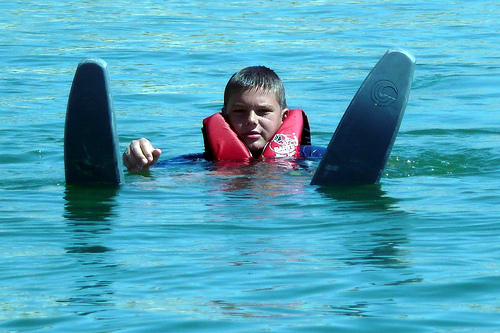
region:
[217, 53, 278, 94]
Person has short hair.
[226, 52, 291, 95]
Person has light brown hair.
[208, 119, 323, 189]
Person wearing red life vest.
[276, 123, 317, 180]
White logo on red vest.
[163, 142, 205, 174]
Person wearing blue shirt.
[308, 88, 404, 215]
Skis sticking out of water.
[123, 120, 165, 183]
Boy's hand is sticking out of water.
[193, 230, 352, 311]
Water is blue in color.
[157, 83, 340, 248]
Boy is in water.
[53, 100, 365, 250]
Boy has skis on feet.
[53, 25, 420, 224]
a boy wearing water boards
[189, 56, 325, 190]
boy has short hair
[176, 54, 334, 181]
boy wears a red lifegurd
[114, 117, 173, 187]
hand above the water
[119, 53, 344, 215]
the body of boy is in the water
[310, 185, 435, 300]
reflections of water ski on the water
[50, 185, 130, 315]
reflections of water ski on the water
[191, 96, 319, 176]
lifeguard vest has a design on right side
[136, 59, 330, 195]
boy wears a blue top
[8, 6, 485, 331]
a boy in a blue ocean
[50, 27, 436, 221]
boy in the water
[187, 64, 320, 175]
boy with a life preserver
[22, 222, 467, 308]
blue waters where boy is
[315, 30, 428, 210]
left water ski on boy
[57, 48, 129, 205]
right water ski on boy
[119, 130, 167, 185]
right hand of a boy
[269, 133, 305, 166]
design on red life preserver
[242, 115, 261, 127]
nose of a boy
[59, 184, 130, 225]
shadow casted in the water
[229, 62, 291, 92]
wet hair on a boy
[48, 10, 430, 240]
a boy in the water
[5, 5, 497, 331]
water color is blue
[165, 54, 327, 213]
boy wearing a life guard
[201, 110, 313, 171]
life guard is color red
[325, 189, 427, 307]
reflection of water ski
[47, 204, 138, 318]
reflection of water ski on left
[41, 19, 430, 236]
boy wearing water skies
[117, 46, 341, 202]
body of boy is summergen in the water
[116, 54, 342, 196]
the right hand of boy can be seen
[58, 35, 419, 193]
Boy floating in water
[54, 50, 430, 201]
Flippers on feet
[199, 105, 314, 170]
Wearing a red life jacket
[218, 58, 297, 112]
Brown hair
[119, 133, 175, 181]
Right hand is out of water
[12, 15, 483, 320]
The water is calm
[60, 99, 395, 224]
Shadows suggest sunny day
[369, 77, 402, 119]
Brand logo on flippers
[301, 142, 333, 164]
Dark shirt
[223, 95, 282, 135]
The boy's eyes are open